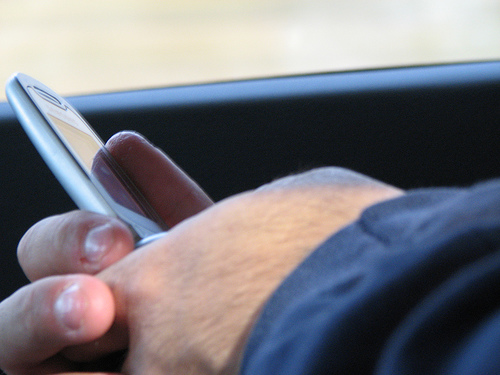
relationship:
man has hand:
[0, 118, 498, 369] [62, 164, 403, 372]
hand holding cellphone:
[62, 164, 403, 372] [6, 75, 166, 249]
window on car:
[5, 3, 498, 96] [0, 3, 498, 303]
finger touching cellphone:
[105, 131, 214, 224] [6, 75, 166, 249]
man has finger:
[0, 118, 498, 369] [14, 213, 142, 283]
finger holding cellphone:
[14, 213, 142, 283] [6, 75, 166, 249]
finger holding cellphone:
[105, 131, 214, 224] [6, 75, 166, 249]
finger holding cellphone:
[0, 268, 111, 373] [6, 75, 166, 249]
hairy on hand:
[144, 179, 365, 371] [62, 164, 403, 372]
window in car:
[5, 3, 498, 96] [0, 3, 498, 303]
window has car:
[5, 3, 498, 96] [0, 0, 499, 303]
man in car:
[0, 118, 498, 369] [0, 3, 498, 303]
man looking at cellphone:
[0, 118, 498, 369] [6, 75, 166, 249]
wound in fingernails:
[76, 253, 93, 265] [82, 220, 116, 260]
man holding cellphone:
[0, 118, 498, 369] [6, 75, 166, 249]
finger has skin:
[0, 268, 111, 373] [108, 136, 139, 162]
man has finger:
[0, 118, 498, 369] [105, 131, 214, 224]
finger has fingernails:
[14, 213, 142, 283] [82, 220, 116, 260]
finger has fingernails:
[0, 268, 111, 373] [54, 284, 83, 332]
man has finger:
[0, 118, 498, 369] [0, 268, 111, 373]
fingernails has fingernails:
[82, 220, 116, 260] [82, 223, 116, 260]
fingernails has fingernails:
[54, 284, 83, 332] [54, 284, 88, 331]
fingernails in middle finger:
[82, 220, 116, 260] [14, 213, 142, 283]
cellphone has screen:
[6, 75, 166, 249] [46, 114, 154, 225]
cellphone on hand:
[6, 75, 166, 249] [62, 164, 403, 372]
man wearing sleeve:
[0, 118, 498, 369] [235, 174, 499, 375]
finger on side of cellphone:
[105, 131, 214, 224] [6, 75, 166, 249]